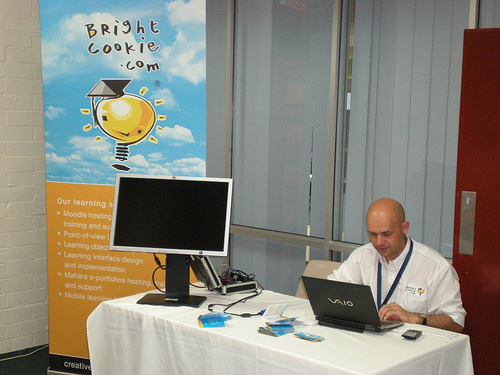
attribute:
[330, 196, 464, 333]
man — bald, balding, working, at event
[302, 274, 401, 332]
laptop — black, vaio brand, gray, viao, open, vaio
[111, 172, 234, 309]
monitor — black, silver, on display, large, flat, free standing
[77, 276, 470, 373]
table — white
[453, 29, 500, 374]
door — red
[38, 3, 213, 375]
bright cookie.com ad — advertisment, large, blue, orange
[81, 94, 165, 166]
light bulb logo — yellow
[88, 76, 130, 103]
graduation cap — black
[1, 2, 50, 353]
wall — white, bricked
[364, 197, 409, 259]
head — bald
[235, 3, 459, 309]
blinds — long, white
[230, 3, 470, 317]
window — indoors, large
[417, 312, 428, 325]
watch — black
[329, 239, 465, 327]
shirt — white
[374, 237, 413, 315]
ribbon — blue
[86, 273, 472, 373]
table cloth — white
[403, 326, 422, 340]
cell phone — black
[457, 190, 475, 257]
handle — silver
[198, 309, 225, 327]
brochure — blue